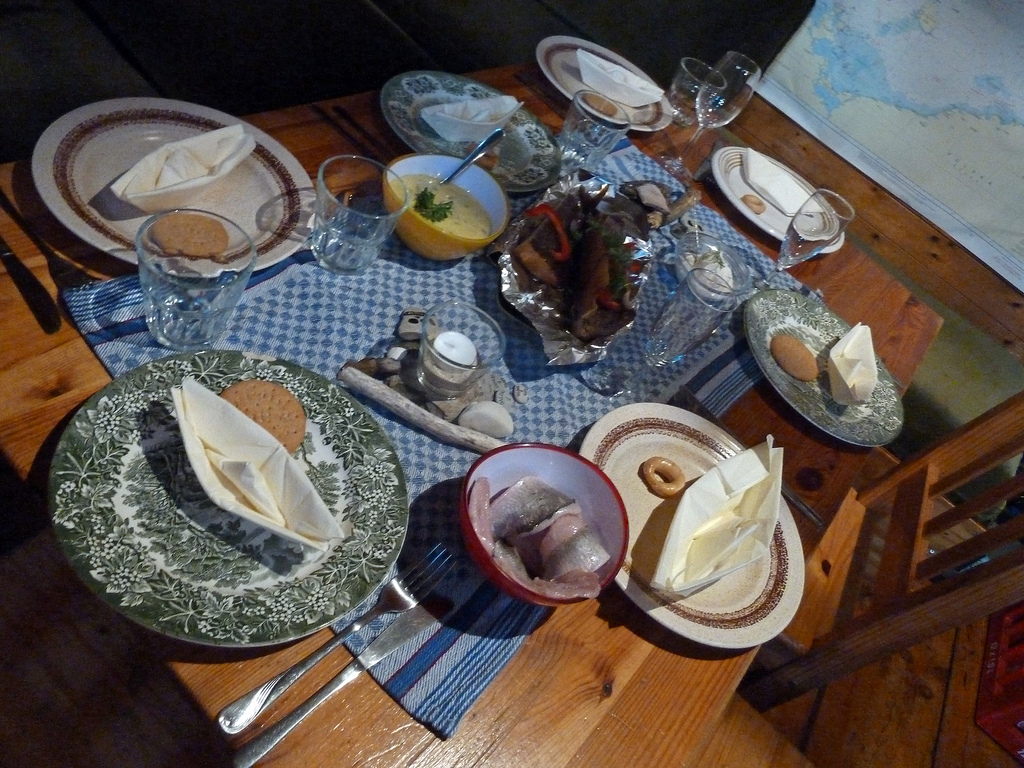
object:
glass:
[134, 208, 258, 352]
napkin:
[170, 378, 346, 551]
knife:
[232, 595, 456, 768]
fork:
[217, 542, 456, 733]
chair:
[736, 390, 1024, 714]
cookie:
[219, 380, 306, 454]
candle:
[433, 331, 479, 374]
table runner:
[63, 119, 825, 738]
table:
[0, 63, 1022, 767]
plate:
[47, 349, 409, 648]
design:
[162, 516, 263, 589]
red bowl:
[458, 442, 630, 607]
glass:
[310, 155, 409, 276]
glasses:
[654, 51, 763, 187]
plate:
[578, 402, 805, 649]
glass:
[416, 299, 507, 399]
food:
[469, 475, 611, 599]